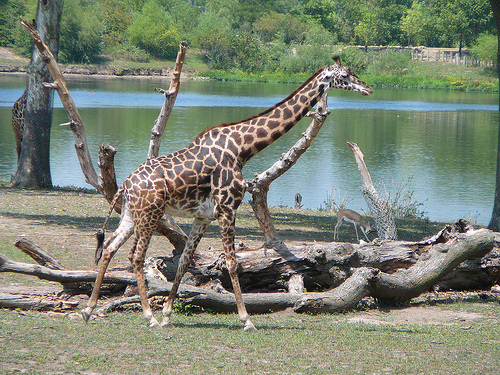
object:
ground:
[3, 202, 72, 230]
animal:
[10, 18, 378, 334]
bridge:
[410, 49, 491, 68]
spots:
[222, 135, 242, 158]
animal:
[333, 209, 378, 244]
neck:
[230, 82, 340, 160]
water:
[274, 90, 496, 222]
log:
[0, 216, 499, 313]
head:
[328, 54, 373, 96]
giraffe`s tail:
[93, 185, 123, 264]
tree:
[202, 29, 285, 86]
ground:
[307, 320, 484, 374]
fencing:
[364, 169, 429, 218]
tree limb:
[344, 139, 397, 239]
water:
[418, 94, 500, 187]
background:
[0, 0, 497, 227]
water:
[90, 84, 336, 141]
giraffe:
[11, 19, 37, 161]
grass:
[7, 316, 25, 373]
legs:
[80, 191, 135, 323]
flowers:
[289, 49, 415, 81]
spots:
[131, 189, 163, 202]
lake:
[0, 67, 499, 223]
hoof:
[244, 323, 260, 333]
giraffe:
[79, 54, 375, 332]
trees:
[396, 0, 474, 47]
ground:
[384, 315, 453, 351]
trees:
[255, 0, 316, 37]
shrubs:
[122, 15, 320, 69]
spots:
[166, 148, 234, 206]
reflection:
[368, 122, 494, 181]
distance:
[194, 9, 262, 65]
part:
[240, 314, 247, 323]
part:
[348, 209, 365, 229]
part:
[371, 328, 401, 355]